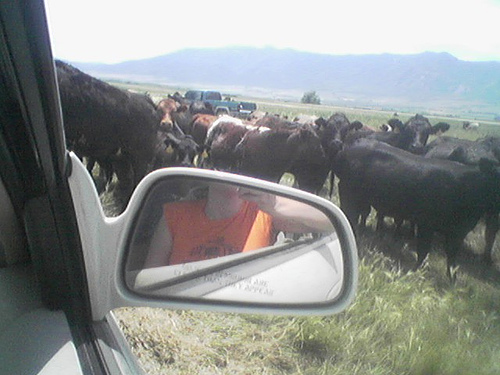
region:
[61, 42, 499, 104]
a mountain range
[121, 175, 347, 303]
reflection of someone wearing an orange shirt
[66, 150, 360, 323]
white side mirror on a vehicle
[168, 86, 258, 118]
a blue truck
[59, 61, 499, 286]
a group of cattle next to a car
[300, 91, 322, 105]
a large green bush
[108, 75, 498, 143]
a clearing at the foot of a mountain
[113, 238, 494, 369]
a grassy area beside a car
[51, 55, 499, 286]
several cows standing in a grassy clearing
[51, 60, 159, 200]
a black cow standing on an object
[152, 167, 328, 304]
Reflection of passenger in car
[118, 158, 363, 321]
Side view mirror on car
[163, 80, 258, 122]
Blue truck behind cows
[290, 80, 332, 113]
Solitary bush behind cows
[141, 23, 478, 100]
Mountain range in background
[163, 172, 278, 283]
Person with orange shirt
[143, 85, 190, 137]
Brown cow facing towards car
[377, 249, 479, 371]
Field of grass beside car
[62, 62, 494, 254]
Herd of cows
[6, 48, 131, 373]
Black stripping of car window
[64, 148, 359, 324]
A white vehicle mirror.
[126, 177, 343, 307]
A reflection in a mirror.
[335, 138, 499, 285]
A black colored cow.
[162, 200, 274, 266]
An orange colored shirt.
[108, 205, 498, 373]
Part of a grassy field.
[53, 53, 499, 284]
A herd of cows.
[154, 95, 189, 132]
A brown cows head.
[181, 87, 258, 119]
A green colored truck.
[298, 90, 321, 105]
A large distant tree.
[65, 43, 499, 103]
A distant mountain range.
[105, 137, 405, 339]
mirror on side of car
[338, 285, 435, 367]
grass on the ground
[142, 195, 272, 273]
orange shirt on mirror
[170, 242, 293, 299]
words on the mirror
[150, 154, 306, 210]
top of the mirror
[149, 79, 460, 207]
cows outside the car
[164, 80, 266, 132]
truck in the distance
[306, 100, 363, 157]
head of a cow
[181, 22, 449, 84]
hills in the background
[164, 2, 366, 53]
sky above the land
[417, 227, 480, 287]
leg of a cow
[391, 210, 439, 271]
leg of a cow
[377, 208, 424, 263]
leg of a cow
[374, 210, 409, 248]
leg of a cow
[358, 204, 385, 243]
leg of a cow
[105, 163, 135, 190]
leg of a cow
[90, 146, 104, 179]
leg of a cow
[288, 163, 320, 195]
leg of a cow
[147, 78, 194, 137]
head of a cow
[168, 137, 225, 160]
head of a cow